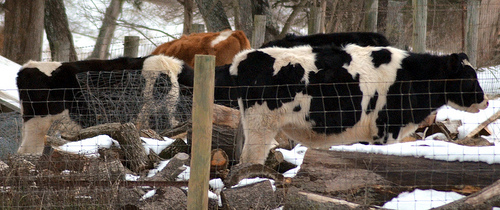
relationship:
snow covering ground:
[0, 53, 499, 208] [3, 130, 496, 208]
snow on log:
[0, 126, 499, 207] [319, 139, 499, 188]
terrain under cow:
[315, 150, 374, 205] [231, 45, 491, 176]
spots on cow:
[289, 50, 390, 121] [231, 45, 491, 176]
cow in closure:
[231, 45, 491, 176] [148, 51, 498, 165]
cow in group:
[231, 45, 491, 176] [12, 31, 492, 191]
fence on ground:
[7, 67, 497, 204] [3, 130, 496, 208]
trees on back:
[0, 0, 490, 59] [293, 4, 498, 49]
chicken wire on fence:
[5, 80, 498, 206] [7, 67, 497, 209]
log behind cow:
[184, 102, 245, 166] [231, 45, 491, 176]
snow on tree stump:
[0, 126, 499, 207] [31, 132, 133, 186]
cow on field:
[16, 59, 239, 156] [4, 140, 498, 203]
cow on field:
[231, 45, 491, 176] [4, 140, 498, 203]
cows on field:
[147, 29, 251, 70] [4, 140, 498, 203]